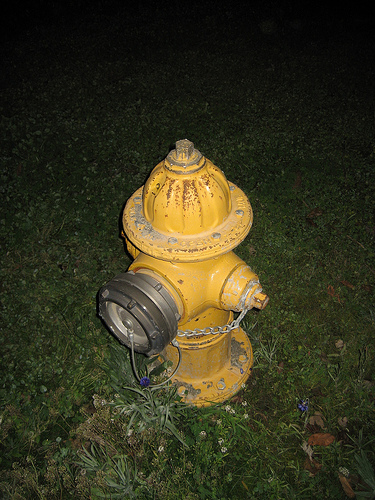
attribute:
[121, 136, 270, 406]
pipe — yellow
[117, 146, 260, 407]
pipe — yellow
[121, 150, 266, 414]
pipe — yellow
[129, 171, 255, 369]
fire hydrant — chipped, painted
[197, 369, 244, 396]
bolt — securing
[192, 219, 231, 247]
bolt — securing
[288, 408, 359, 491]
leaves — fallen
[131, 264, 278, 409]
hydrant — rusted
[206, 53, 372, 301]
field — large, grassy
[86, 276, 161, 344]
hydrant — silver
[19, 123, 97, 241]
grass — dark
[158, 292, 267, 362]
chain — silver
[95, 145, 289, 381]
hydrant — yellow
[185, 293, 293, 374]
chain — silver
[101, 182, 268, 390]
hydrant — gray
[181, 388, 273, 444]
flowers — small, white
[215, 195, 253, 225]
bolts — silver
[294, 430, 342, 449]
leaf — one, brown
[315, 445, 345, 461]
grass — green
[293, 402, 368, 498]
leaves — brown